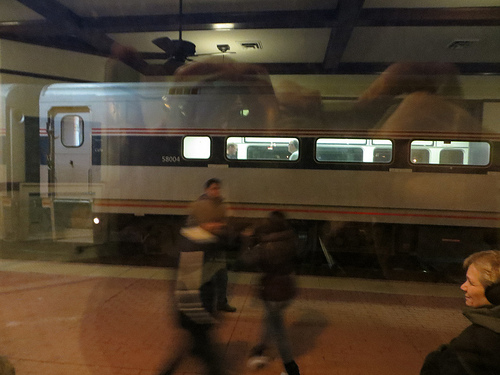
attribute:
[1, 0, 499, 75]
ceiling — white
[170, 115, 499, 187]
windows — lighted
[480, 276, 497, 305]
ear muffs — black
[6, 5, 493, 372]
window — glass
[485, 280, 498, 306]
muffs — black, ear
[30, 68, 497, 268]
train — door, in full view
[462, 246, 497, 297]
hair — blond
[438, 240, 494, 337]
view — side, person's head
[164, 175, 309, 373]
people — in foreground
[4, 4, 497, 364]
station — train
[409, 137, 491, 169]
window — small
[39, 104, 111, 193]
door — silver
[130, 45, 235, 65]
ceiling fan — small, black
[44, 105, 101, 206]
door — gray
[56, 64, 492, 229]
train — side view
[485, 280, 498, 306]
ear muffs — black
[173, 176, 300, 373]
people — in foreground, blurred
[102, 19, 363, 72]
ceiling — white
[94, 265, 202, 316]
brick — red